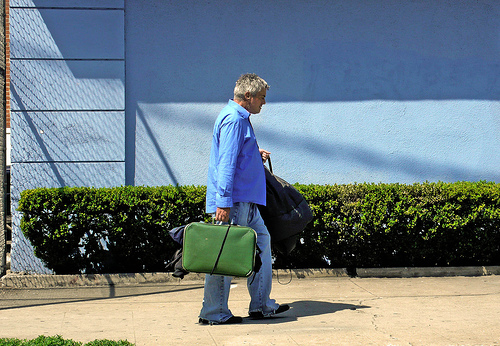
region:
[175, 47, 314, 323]
a man carrying a green suitcase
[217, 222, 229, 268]
a black cord on the suircase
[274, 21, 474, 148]
a blue wall next to the man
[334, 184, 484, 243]
green shrubbery next to the wall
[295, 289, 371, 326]
a shadow on the sidewalk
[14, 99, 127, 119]
a line in the wall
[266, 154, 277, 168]
the strap on backpack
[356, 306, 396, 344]
a crack in the sidewalk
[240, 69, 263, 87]
gray hair on a head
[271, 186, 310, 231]
a blue bag dangling in front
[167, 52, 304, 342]
A man walking with a bag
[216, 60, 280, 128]
A head of a man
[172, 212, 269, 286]
This is a green bag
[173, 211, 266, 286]
This is a green suitcase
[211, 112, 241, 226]
This is a hand of a man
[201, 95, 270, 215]
This is a blue sky shirt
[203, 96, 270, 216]
This is a blue shirt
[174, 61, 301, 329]
This is a man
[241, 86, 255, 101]
This is an ear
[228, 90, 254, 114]
This is a neck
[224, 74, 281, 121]
man with blonde hair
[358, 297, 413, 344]
large crack in concrete path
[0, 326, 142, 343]
grass growing beside path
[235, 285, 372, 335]
shadow of man on path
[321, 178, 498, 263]
row of hedges with green leaves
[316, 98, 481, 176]
blue paint on wall beside path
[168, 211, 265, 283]
green suitcase being carried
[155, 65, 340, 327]
man in blue clothing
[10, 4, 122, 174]
shadow of fencing on wall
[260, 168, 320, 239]
black backpack being carried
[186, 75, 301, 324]
Man walking on sidewalk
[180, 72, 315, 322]
man wearing blue jeans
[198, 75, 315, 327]
man wearing blue shirt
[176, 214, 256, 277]
man carrying green suitcase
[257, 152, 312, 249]
man carrying black bag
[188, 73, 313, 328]
man wearing black shoes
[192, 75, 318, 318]
man has gray hair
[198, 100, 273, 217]
man's shirt is untucked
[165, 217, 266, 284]
clothing sticking out of suitcase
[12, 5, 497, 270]
concrete wall is blue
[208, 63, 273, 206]
Man wearing blue shirt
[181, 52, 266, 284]
Man in blue shirt carrying green suitcase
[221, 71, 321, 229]
Man in blue shirt carrying black bag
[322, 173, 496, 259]
Neatly trimmed hedges beside blue wall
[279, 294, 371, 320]
Man's shadow on sidewalk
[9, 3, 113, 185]
Fence shadow on blue wall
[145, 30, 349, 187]
Bright blue wall beside man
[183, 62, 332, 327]
Man in blue shirt and jeans carrying bags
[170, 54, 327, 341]
Man in blue shirt walking on sidewalk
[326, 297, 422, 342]
Large crack on sidewalk